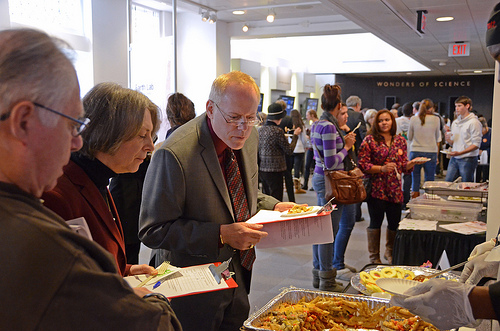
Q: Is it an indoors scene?
A: Yes, it is indoors.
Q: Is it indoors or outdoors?
A: It is indoors.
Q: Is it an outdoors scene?
A: No, it is indoors.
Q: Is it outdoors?
A: No, it is indoors.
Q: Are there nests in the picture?
A: No, there are no nests.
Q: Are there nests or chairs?
A: No, there are no nests or chairs.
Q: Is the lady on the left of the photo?
A: Yes, the lady is on the left of the image.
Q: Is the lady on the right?
A: No, the lady is on the left of the image.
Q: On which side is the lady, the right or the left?
A: The lady is on the left of the image.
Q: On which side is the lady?
A: The lady is on the left of the image.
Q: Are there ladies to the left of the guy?
A: Yes, there is a lady to the left of the guy.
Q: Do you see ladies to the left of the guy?
A: Yes, there is a lady to the left of the guy.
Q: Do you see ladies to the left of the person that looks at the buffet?
A: Yes, there is a lady to the left of the guy.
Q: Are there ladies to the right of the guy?
A: No, the lady is to the left of the guy.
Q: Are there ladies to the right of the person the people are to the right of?
A: No, the lady is to the left of the guy.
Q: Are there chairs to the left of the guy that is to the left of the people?
A: No, there is a lady to the left of the guy.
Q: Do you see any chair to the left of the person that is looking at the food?
A: No, there is a lady to the left of the guy.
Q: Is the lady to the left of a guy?
A: Yes, the lady is to the left of a guy.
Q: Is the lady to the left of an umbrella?
A: No, the lady is to the left of a guy.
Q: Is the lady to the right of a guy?
A: No, the lady is to the left of a guy.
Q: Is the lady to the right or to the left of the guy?
A: The lady is to the left of the guy.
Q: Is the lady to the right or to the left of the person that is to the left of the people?
A: The lady is to the left of the guy.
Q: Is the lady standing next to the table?
A: Yes, the lady is standing next to the table.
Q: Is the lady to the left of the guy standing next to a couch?
A: No, the lady is standing next to the table.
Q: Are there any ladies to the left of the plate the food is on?
A: Yes, there is a lady to the left of the plate.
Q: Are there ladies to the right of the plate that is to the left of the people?
A: No, the lady is to the left of the plate.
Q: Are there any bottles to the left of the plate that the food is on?
A: No, there is a lady to the left of the plate.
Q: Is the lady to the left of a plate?
A: Yes, the lady is to the left of a plate.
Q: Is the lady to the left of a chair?
A: No, the lady is to the left of a plate.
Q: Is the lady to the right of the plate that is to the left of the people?
A: No, the lady is to the left of the plate.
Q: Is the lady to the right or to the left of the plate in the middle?
A: The lady is to the left of the plate.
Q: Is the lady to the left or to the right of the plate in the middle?
A: The lady is to the left of the plate.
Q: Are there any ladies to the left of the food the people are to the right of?
A: Yes, there is a lady to the left of the food.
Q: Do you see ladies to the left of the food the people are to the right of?
A: Yes, there is a lady to the left of the food.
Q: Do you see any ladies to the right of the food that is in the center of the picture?
A: No, the lady is to the left of the food.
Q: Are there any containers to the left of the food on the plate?
A: No, there is a lady to the left of the food.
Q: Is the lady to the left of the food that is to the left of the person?
A: Yes, the lady is to the left of the food.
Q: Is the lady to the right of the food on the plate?
A: No, the lady is to the left of the food.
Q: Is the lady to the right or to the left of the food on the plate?
A: The lady is to the left of the food.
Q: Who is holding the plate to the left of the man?
A: The lady is holding the plate.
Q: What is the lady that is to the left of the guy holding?
A: The lady is holding the plate.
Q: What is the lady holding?
A: The lady is holding the plate.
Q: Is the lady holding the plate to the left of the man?
A: Yes, the lady is holding the plate.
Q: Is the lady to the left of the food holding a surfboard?
A: No, the lady is holding the plate.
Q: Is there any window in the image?
A: Yes, there is a window.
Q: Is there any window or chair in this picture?
A: Yes, there is a window.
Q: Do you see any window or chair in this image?
A: Yes, there is a window.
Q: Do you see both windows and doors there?
A: No, there is a window but no doors.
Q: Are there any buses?
A: No, there are no buses.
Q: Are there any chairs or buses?
A: No, there are no buses or chairs.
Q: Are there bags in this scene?
A: Yes, there is a bag.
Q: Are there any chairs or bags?
A: Yes, there is a bag.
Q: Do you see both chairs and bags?
A: No, there is a bag but no chairs.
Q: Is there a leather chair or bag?
A: Yes, there is a leather bag.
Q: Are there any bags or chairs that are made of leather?
A: Yes, the bag is made of leather.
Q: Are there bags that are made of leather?
A: Yes, there is a bag that is made of leather.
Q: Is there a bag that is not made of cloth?
A: Yes, there is a bag that is made of leather.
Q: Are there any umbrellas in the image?
A: No, there are no umbrellas.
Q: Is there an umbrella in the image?
A: No, there are no umbrellas.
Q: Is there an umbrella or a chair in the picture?
A: No, there are no umbrellas or chairs.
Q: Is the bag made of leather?
A: Yes, the bag is made of leather.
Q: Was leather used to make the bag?
A: Yes, the bag is made of leather.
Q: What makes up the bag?
A: The bag is made of leather.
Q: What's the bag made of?
A: The bag is made of leather.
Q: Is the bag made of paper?
A: No, the bag is made of leather.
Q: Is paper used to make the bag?
A: No, the bag is made of leather.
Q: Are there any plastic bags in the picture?
A: No, there is a bag but it is made of leather.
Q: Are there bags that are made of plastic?
A: No, there is a bag but it is made of leather.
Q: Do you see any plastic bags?
A: No, there is a bag but it is made of leather.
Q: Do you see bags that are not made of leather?
A: No, there is a bag but it is made of leather.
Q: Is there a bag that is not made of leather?
A: No, there is a bag but it is made of leather.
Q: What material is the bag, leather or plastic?
A: The bag is made of leather.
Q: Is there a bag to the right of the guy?
A: Yes, there is a bag to the right of the guy.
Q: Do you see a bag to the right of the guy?
A: Yes, there is a bag to the right of the guy.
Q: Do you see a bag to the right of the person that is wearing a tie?
A: Yes, there is a bag to the right of the guy.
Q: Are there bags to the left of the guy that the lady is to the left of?
A: No, the bag is to the right of the guy.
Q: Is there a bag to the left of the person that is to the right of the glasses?
A: No, the bag is to the right of the guy.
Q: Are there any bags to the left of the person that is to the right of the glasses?
A: No, the bag is to the right of the guy.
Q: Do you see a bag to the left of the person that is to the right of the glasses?
A: No, the bag is to the right of the guy.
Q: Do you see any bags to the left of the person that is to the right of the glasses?
A: No, the bag is to the right of the guy.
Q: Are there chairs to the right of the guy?
A: No, there is a bag to the right of the guy.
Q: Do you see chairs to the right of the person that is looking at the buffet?
A: No, there is a bag to the right of the guy.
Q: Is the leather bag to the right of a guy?
A: Yes, the bag is to the right of a guy.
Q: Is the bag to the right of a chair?
A: No, the bag is to the right of a guy.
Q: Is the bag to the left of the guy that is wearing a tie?
A: No, the bag is to the right of the guy.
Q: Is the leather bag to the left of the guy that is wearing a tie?
A: No, the bag is to the right of the guy.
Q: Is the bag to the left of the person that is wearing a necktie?
A: No, the bag is to the right of the guy.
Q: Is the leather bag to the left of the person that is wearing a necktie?
A: No, the bag is to the right of the guy.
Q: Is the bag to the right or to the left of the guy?
A: The bag is to the right of the guy.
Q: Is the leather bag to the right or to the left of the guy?
A: The bag is to the right of the guy.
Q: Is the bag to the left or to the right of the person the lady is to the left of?
A: The bag is to the right of the guy.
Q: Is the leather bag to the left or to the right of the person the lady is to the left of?
A: The bag is to the right of the guy.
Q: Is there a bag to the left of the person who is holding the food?
A: Yes, there is a bag to the left of the person.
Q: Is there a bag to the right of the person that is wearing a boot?
A: No, the bag is to the left of the person.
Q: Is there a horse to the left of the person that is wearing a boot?
A: No, there is a bag to the left of the person.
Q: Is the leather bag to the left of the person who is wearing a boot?
A: Yes, the bag is to the left of the person.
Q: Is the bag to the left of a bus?
A: No, the bag is to the left of the person.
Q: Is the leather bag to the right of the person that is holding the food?
A: No, the bag is to the left of the person.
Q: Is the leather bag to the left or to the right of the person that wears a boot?
A: The bag is to the left of the person.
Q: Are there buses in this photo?
A: No, there are no buses.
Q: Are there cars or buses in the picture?
A: No, there are no buses or cars.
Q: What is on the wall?
A: The sign is on the wall.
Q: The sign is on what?
A: The sign is on the wall.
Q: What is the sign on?
A: The sign is on the wall.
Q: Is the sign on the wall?
A: Yes, the sign is on the wall.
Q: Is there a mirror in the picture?
A: No, there are no mirrors.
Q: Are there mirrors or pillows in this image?
A: No, there are no mirrors or pillows.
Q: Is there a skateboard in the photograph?
A: No, there are no skateboards.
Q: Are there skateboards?
A: No, there are no skateboards.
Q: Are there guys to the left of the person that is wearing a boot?
A: Yes, there is a guy to the left of the person.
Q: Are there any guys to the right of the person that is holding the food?
A: No, the guy is to the left of the person.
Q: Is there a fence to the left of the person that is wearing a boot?
A: No, there is a guy to the left of the person.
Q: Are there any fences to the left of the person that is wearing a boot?
A: No, there is a guy to the left of the person.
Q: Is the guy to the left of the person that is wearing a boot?
A: Yes, the guy is to the left of the person.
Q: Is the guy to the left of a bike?
A: No, the guy is to the left of the person.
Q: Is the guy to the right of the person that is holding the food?
A: No, the guy is to the left of the person.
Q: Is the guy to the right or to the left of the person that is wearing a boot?
A: The guy is to the left of the person.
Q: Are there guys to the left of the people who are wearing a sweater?
A: Yes, there is a guy to the left of the people.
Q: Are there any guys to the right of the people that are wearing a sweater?
A: No, the guy is to the left of the people.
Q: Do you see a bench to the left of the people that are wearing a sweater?
A: No, there is a guy to the left of the people.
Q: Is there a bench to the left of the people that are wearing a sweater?
A: No, there is a guy to the left of the people.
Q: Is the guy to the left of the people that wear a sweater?
A: Yes, the guy is to the left of the people.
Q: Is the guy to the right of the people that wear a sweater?
A: No, the guy is to the left of the people.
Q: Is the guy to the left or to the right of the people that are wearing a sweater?
A: The guy is to the left of the people.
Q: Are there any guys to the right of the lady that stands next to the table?
A: Yes, there is a guy to the right of the lady.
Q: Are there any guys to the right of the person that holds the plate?
A: Yes, there is a guy to the right of the lady.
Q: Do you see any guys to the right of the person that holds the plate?
A: Yes, there is a guy to the right of the lady.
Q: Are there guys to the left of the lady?
A: No, the guy is to the right of the lady.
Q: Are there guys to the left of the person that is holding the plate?
A: No, the guy is to the right of the lady.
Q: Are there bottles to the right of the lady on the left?
A: No, there is a guy to the right of the lady.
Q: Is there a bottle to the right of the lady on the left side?
A: No, there is a guy to the right of the lady.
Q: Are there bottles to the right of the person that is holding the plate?
A: No, there is a guy to the right of the lady.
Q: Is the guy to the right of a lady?
A: Yes, the guy is to the right of a lady.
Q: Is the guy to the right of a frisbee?
A: No, the guy is to the right of a lady.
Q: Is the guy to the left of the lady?
A: No, the guy is to the right of the lady.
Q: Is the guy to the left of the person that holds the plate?
A: No, the guy is to the right of the lady.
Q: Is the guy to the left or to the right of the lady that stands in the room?
A: The guy is to the right of the lady.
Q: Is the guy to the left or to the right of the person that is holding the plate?
A: The guy is to the right of the lady.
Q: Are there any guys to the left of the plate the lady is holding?
A: Yes, there is a guy to the left of the plate.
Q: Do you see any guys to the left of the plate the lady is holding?
A: Yes, there is a guy to the left of the plate.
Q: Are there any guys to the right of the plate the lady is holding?
A: No, the guy is to the left of the plate.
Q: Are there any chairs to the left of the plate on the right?
A: No, there is a guy to the left of the plate.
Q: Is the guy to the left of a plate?
A: Yes, the guy is to the left of a plate.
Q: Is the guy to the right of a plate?
A: No, the guy is to the left of a plate.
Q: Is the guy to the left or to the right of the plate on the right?
A: The guy is to the left of the plate.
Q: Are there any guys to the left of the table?
A: Yes, there is a guy to the left of the table.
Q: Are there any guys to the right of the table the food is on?
A: No, the guy is to the left of the table.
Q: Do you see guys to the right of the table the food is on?
A: No, the guy is to the left of the table.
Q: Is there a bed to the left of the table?
A: No, there is a guy to the left of the table.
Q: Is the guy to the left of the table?
A: Yes, the guy is to the left of the table.